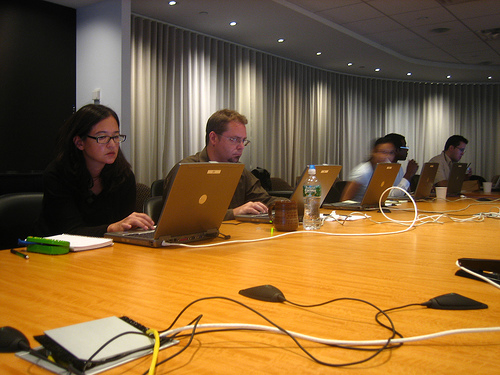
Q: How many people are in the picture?
A: Five people.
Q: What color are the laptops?
A: Grey.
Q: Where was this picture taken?
A: Office.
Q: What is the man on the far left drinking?
A: Water.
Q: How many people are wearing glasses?
A: 4.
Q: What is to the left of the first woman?
A: Notebook.